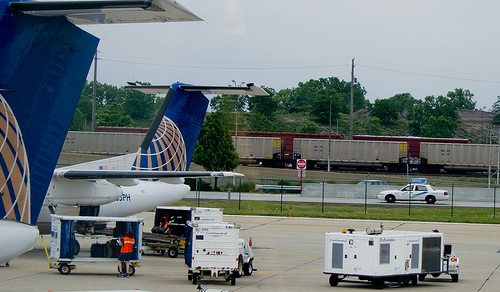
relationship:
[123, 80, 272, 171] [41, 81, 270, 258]
plane tail on airplane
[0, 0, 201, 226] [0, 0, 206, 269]
tail-fin on jet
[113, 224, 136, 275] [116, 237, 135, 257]
luggage handler wearing vest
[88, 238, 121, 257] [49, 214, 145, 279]
luggage on cart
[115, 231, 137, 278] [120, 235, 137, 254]
man wearing vest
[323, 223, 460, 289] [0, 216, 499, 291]
truck on tarmac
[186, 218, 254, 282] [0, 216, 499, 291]
truck on tarmac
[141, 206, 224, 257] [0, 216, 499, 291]
truck on tarmac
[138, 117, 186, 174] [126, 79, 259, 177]
globe on plane tail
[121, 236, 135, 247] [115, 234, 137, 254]
stripe on vest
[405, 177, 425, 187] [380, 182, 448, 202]
sign on car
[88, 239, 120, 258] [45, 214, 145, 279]
luggage in cart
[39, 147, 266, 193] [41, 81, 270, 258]
right wing of airplane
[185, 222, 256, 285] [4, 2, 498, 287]
truck at airport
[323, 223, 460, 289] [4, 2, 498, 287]
truck at airport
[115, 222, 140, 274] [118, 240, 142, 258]
man wearing vest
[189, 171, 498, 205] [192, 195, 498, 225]
fence beside grass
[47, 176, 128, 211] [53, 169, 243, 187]
engine under right wing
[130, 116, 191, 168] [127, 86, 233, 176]
logo on plane tail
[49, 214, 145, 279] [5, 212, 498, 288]
cart near airport runway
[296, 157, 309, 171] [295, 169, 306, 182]
sign on pole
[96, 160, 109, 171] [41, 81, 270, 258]
american flag on a airplane